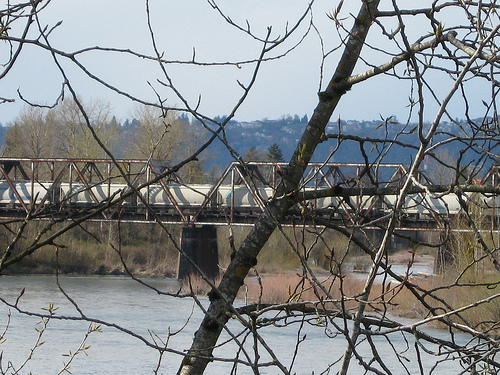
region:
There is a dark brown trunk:
[203, 246, 255, 360]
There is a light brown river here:
[96, 280, 115, 330]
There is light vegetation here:
[342, 275, 350, 290]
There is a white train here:
[171, 188, 184, 221]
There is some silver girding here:
[93, 145, 100, 182]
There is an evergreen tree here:
[272, 148, 277, 163]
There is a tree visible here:
[58, 108, 77, 163]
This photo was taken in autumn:
[120, 81, 352, 358]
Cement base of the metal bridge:
[171, 228, 226, 285]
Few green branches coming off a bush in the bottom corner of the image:
[0, 288, 125, 373]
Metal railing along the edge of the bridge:
[1, 153, 160, 229]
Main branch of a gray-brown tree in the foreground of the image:
[167, 0, 392, 374]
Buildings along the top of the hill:
[218, 113, 498, 149]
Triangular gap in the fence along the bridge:
[150, 157, 230, 213]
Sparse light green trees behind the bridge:
[5, 95, 195, 190]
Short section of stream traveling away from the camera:
[215, 245, 456, 285]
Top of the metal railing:
[220, 154, 426, 179]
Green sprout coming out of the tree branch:
[292, 135, 310, 165]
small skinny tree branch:
[425, 279, 486, 346]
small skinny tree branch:
[330, 315, 380, 373]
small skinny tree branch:
[142, 209, 232, 309]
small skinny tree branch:
[54, 282, 142, 372]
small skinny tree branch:
[32, 273, 99, 327]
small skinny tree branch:
[67, 96, 139, 187]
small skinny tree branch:
[102, 66, 167, 130]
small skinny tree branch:
[82, 39, 139, 69]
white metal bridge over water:
[0, 142, 498, 240]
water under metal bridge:
[8, 138, 339, 373]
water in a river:
[27, 269, 196, 372]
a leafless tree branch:
[263, 9, 498, 369]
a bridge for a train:
[5, 140, 449, 237]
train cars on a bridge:
[8, 141, 497, 243]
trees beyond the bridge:
[18, 104, 198, 184]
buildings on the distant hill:
[232, 115, 430, 150]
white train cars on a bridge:
[2, 166, 459, 219]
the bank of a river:
[19, 251, 174, 285]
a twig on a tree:
[48, 244, 86, 318]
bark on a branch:
[198, 245, 234, 359]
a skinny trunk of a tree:
[223, 202, 282, 264]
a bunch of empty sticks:
[267, 300, 307, 336]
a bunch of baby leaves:
[60, 321, 102, 358]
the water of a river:
[97, 266, 159, 340]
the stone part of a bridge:
[82, 204, 137, 275]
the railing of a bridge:
[77, 156, 133, 218]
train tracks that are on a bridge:
[118, 157, 178, 225]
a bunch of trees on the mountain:
[217, 109, 284, 154]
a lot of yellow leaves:
[20, 111, 99, 156]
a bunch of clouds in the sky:
[155, 5, 208, 45]